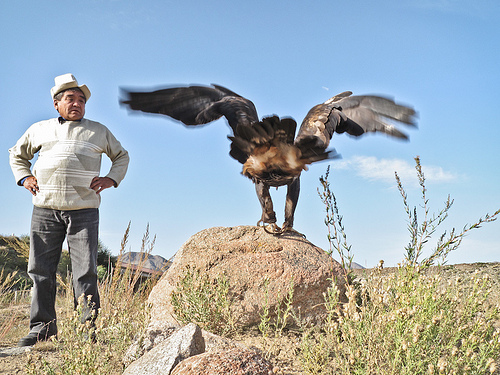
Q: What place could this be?
A: It is a field.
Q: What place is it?
A: It is a field.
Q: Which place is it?
A: It is a field.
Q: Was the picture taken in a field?
A: Yes, it was taken in a field.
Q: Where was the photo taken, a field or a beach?
A: It was taken at a field.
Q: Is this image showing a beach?
A: No, the picture is showing a field.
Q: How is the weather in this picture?
A: It is clear.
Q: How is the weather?
A: It is clear.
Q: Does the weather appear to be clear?
A: Yes, it is clear.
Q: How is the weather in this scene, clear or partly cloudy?
A: It is clear.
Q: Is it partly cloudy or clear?
A: It is clear.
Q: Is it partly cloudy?
A: No, it is clear.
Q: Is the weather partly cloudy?
A: No, it is clear.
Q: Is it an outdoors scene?
A: Yes, it is outdoors.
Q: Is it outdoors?
A: Yes, it is outdoors.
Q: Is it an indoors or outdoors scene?
A: It is outdoors.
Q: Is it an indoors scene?
A: No, it is outdoors.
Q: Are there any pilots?
A: No, there are no pilots.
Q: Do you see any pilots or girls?
A: No, there are no pilots or girls.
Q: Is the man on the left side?
A: Yes, the man is on the left of the image.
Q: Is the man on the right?
A: No, the man is on the left of the image.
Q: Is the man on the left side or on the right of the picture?
A: The man is on the left of the image.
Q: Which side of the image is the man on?
A: The man is on the left of the image.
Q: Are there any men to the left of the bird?
A: Yes, there is a man to the left of the bird.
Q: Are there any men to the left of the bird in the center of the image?
A: Yes, there is a man to the left of the bird.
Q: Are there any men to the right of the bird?
A: No, the man is to the left of the bird.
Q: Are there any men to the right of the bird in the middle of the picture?
A: No, the man is to the left of the bird.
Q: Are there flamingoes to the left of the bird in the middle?
A: No, there is a man to the left of the bird.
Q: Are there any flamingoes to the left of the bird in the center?
A: No, there is a man to the left of the bird.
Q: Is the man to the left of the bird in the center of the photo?
A: Yes, the man is to the left of the bird.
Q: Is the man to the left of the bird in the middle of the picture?
A: Yes, the man is to the left of the bird.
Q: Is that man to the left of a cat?
A: No, the man is to the left of the bird.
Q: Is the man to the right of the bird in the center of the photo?
A: No, the man is to the left of the bird.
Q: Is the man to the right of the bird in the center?
A: No, the man is to the left of the bird.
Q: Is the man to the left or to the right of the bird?
A: The man is to the left of the bird.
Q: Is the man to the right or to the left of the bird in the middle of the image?
A: The man is to the left of the bird.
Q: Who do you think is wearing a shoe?
A: The man is wearing a shoe.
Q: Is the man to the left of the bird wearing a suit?
A: No, the man is wearing a shoe.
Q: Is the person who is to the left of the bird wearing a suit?
A: No, the man is wearing a shoe.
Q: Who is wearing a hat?
A: The man is wearing a hat.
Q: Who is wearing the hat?
A: The man is wearing a hat.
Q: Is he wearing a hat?
A: Yes, the man is wearing a hat.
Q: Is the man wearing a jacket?
A: No, the man is wearing a hat.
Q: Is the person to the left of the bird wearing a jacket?
A: No, the man is wearing a hat.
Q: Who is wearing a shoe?
A: The man is wearing a shoe.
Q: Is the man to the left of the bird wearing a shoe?
A: Yes, the man is wearing a shoe.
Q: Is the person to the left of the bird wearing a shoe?
A: Yes, the man is wearing a shoe.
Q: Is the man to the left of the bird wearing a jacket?
A: No, the man is wearing a shoe.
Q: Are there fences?
A: No, there are no fences.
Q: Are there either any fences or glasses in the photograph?
A: No, there are no fences or glasses.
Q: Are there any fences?
A: No, there are no fences.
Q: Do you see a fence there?
A: No, there are no fences.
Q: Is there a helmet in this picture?
A: No, there are no helmets.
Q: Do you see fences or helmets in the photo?
A: No, there are no helmets or fences.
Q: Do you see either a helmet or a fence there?
A: No, there are no helmets or fences.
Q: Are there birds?
A: Yes, there is a bird.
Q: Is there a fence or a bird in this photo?
A: Yes, there is a bird.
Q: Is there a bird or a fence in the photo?
A: Yes, there is a bird.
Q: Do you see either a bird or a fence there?
A: Yes, there is a bird.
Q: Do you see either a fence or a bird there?
A: Yes, there is a bird.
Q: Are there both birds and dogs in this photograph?
A: No, there is a bird but no dogs.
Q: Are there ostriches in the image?
A: No, there are no ostriches.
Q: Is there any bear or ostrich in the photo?
A: No, there are no ostriches or bears.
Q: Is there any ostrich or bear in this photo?
A: No, there are no ostriches or bears.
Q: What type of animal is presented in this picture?
A: The animal is a bird.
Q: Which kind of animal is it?
A: The animal is a bird.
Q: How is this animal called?
A: This is a bird.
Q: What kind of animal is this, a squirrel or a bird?
A: This is a bird.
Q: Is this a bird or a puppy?
A: This is a bird.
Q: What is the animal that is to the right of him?
A: The animal is a bird.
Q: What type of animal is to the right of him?
A: The animal is a bird.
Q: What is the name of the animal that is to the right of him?
A: The animal is a bird.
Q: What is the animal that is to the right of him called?
A: The animal is a bird.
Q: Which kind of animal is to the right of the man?
A: The animal is a bird.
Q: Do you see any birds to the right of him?
A: Yes, there is a bird to the right of the man.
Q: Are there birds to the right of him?
A: Yes, there is a bird to the right of the man.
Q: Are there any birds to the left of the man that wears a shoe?
A: No, the bird is to the right of the man.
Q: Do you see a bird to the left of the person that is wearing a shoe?
A: No, the bird is to the right of the man.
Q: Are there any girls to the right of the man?
A: No, there is a bird to the right of the man.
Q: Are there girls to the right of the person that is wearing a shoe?
A: No, there is a bird to the right of the man.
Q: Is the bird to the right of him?
A: Yes, the bird is to the right of a man.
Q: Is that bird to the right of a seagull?
A: No, the bird is to the right of a man.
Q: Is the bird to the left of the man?
A: No, the bird is to the right of the man.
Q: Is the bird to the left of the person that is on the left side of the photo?
A: No, the bird is to the right of the man.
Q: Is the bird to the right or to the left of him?
A: The bird is to the right of the man.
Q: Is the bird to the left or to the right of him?
A: The bird is to the right of the man.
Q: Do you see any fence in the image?
A: No, there are no fences.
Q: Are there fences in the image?
A: No, there are no fences.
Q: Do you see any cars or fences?
A: No, there are no fences or cars.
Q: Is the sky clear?
A: Yes, the sky is clear.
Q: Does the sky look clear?
A: Yes, the sky is clear.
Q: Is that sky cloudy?
A: No, the sky is clear.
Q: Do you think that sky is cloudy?
A: No, the sky is clear.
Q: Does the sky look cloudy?
A: No, the sky is clear.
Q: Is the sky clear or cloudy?
A: The sky is clear.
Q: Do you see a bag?
A: No, there are no bags.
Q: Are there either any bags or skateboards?
A: No, there are no bags or skateboards.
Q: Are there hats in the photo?
A: Yes, there is a hat.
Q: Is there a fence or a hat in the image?
A: Yes, there is a hat.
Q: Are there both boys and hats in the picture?
A: No, there is a hat but no boys.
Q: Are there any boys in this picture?
A: No, there are no boys.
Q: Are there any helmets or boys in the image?
A: No, there are no boys or helmets.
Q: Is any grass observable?
A: Yes, there is grass.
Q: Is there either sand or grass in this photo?
A: Yes, there is grass.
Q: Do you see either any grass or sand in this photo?
A: Yes, there is grass.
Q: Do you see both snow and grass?
A: No, there is grass but no snow.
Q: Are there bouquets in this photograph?
A: No, there are no bouquets.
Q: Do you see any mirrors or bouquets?
A: No, there are no bouquets or mirrors.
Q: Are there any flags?
A: No, there are no flags.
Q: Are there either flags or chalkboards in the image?
A: No, there are no flags or chalkboards.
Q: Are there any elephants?
A: No, there are no elephants.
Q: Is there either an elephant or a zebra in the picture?
A: No, there are no elephants or zebras.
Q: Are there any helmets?
A: No, there are no helmets.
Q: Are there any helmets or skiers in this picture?
A: No, there are no helmets or skiers.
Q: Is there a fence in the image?
A: No, there are no fences.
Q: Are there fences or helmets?
A: No, there are no fences or helmets.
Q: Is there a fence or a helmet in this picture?
A: No, there are no fences or helmets.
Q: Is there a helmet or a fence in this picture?
A: No, there are no fences or helmets.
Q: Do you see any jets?
A: No, there are no jets.